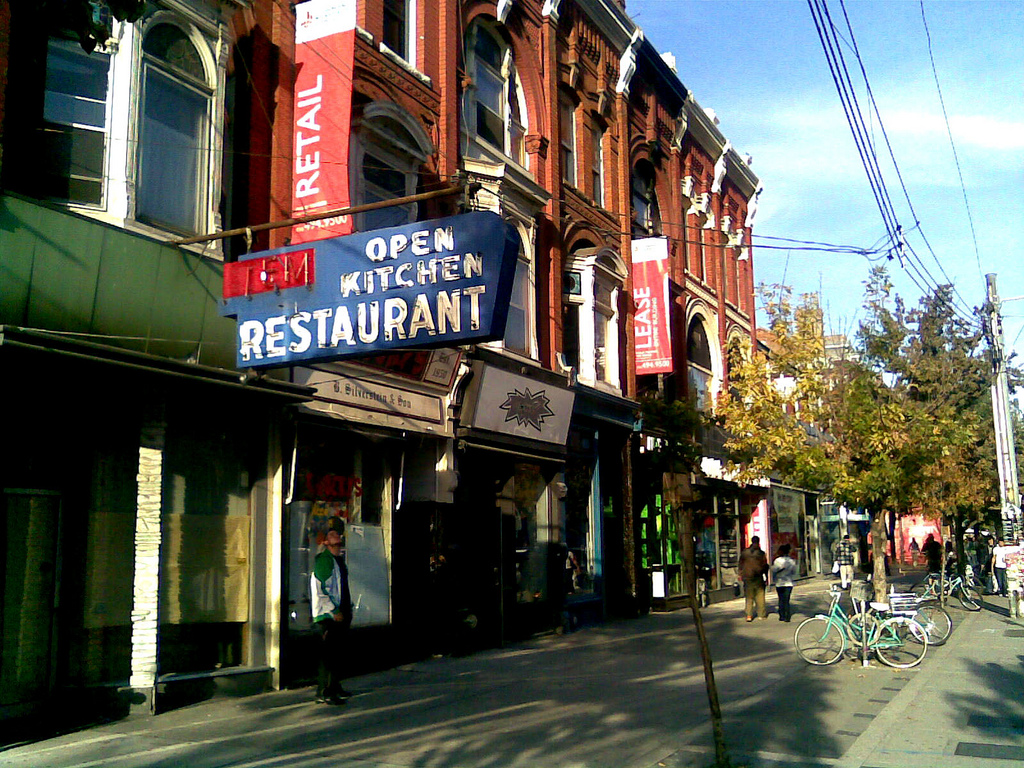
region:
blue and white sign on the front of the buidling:
[229, 244, 501, 343]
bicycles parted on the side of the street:
[817, 575, 941, 677]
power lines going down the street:
[790, 23, 983, 302]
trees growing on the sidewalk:
[811, 335, 993, 601]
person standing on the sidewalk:
[261, 503, 363, 713]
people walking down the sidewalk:
[738, 531, 795, 618]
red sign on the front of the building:
[624, 222, 683, 397]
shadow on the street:
[954, 631, 1011, 762]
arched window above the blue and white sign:
[139, 7, 244, 229]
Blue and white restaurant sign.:
[221, 205, 509, 373]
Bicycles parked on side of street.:
[793, 574, 955, 682]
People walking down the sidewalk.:
[735, 534, 800, 629]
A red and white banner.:
[632, 227, 672, 387]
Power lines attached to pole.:
[796, 12, 1022, 521]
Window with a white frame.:
[103, 10, 237, 233]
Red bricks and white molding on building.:
[343, 0, 770, 380]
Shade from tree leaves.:
[381, 625, 891, 765]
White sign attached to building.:
[467, 357, 578, 459]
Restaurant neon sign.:
[207, 203, 527, 358]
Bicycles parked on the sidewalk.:
[791, 577, 988, 673]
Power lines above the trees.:
[775, 2, 1006, 320]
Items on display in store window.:
[270, 413, 423, 664]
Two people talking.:
[721, 512, 797, 615]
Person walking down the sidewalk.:
[819, 517, 857, 587]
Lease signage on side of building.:
[624, 223, 676, 378]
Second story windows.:
[2, 0, 222, 263]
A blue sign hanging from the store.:
[208, 225, 528, 387]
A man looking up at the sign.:
[297, 515, 386, 702]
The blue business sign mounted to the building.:
[229, 202, 521, 379]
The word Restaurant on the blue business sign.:
[236, 291, 505, 352]